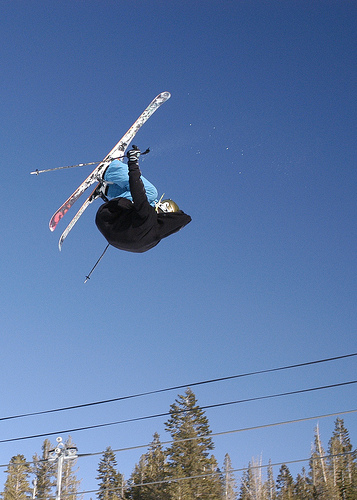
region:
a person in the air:
[24, 88, 250, 302]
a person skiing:
[15, 80, 243, 316]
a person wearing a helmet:
[22, 87, 195, 300]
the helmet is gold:
[148, 189, 189, 232]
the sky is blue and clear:
[256, 185, 340, 307]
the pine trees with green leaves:
[2, 388, 355, 499]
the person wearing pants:
[91, 146, 215, 274]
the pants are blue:
[86, 159, 166, 208]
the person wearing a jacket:
[96, 148, 209, 264]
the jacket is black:
[91, 161, 199, 272]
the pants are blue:
[106, 163, 154, 205]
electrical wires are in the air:
[107, 382, 246, 484]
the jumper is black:
[95, 200, 188, 253]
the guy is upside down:
[65, 152, 211, 265]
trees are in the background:
[24, 437, 353, 491]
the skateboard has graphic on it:
[106, 125, 157, 141]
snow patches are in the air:
[165, 115, 269, 178]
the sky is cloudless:
[225, 410, 312, 450]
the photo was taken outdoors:
[11, 139, 356, 499]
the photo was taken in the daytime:
[3, 11, 356, 488]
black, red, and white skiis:
[47, 90, 169, 250]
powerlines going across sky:
[0, 349, 355, 496]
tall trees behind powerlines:
[1, 387, 355, 497]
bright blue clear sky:
[151, 340, 204, 357]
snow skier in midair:
[94, 142, 192, 254]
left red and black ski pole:
[28, 146, 151, 175]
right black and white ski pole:
[80, 244, 109, 283]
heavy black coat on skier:
[93, 165, 192, 253]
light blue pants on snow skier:
[103, 159, 159, 203]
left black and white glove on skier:
[125, 144, 140, 163]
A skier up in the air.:
[2, 80, 222, 296]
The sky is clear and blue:
[8, 9, 351, 449]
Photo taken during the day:
[11, 8, 345, 489]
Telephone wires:
[14, 346, 349, 472]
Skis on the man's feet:
[50, 47, 186, 252]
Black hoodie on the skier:
[88, 152, 208, 273]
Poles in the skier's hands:
[21, 112, 152, 283]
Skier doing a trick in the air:
[26, 68, 223, 270]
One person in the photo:
[21, 55, 227, 307]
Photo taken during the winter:
[33, 11, 346, 477]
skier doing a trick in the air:
[16, 75, 208, 285]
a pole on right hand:
[71, 238, 113, 291]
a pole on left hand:
[26, 144, 157, 179]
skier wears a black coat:
[85, 141, 202, 265]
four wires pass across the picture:
[5, 325, 355, 498]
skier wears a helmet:
[139, 186, 190, 254]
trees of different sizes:
[9, 386, 354, 498]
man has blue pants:
[77, 143, 202, 266]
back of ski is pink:
[35, 188, 75, 233]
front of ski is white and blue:
[128, 85, 177, 151]